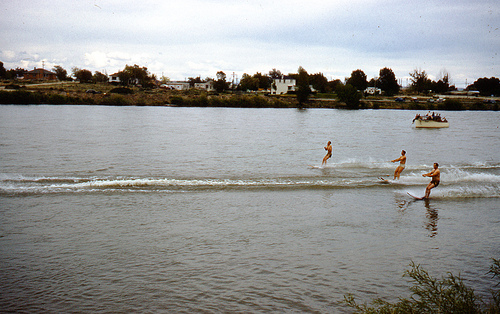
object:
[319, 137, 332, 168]
woman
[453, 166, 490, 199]
ocean waves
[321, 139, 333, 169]
man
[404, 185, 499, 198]
wave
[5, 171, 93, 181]
wave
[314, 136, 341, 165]
people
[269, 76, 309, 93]
house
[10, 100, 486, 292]
water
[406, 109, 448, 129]
boat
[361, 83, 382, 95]
house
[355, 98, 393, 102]
bank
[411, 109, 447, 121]
people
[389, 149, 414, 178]
man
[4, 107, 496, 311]
river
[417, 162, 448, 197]
man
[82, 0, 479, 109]
sky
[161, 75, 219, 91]
house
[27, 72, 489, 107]
river bank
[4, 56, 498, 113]
town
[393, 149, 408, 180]
surfers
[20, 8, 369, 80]
clouds